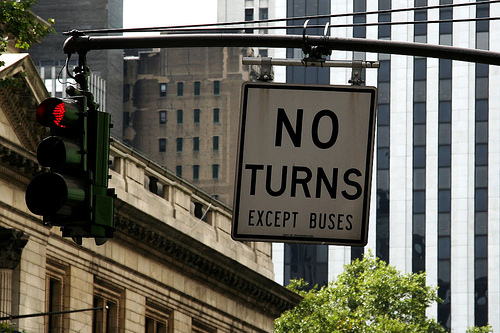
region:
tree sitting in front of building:
[270, 256, 496, 331]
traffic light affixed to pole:
[20, 26, 495, 247]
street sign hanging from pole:
[229, 57, 386, 239]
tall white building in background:
[213, 0, 498, 332]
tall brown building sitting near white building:
[122, 30, 268, 245]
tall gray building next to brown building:
[0, 0, 122, 141]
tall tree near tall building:
[0, 0, 54, 63]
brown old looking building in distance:
[116, 22, 273, 259]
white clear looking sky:
[116, 0, 227, 40]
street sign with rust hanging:
[227, 85, 379, 238]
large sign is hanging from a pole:
[231, 30, 381, 250]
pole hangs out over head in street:
[61, 20, 496, 72]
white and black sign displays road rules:
[227, 41, 377, 243]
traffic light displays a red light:
[18, 91, 119, 246]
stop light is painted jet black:
[18, 25, 125, 249]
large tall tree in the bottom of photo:
[273, 251, 494, 332]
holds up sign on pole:
[240, 23, 375, 84]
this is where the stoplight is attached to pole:
[54, 28, 100, 92]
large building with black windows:
[272, 0, 498, 329]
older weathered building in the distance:
[118, 22, 270, 214]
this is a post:
[228, 79, 369, 241]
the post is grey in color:
[340, 94, 367, 138]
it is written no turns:
[244, 95, 369, 212]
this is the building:
[112, 185, 217, 330]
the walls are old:
[155, 275, 191, 300]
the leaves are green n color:
[333, 271, 409, 331]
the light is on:
[38, 98, 70, 133]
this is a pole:
[317, 32, 374, 59]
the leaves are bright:
[344, 266, 409, 330]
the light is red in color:
[49, 101, 62, 118]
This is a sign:
[177, 49, 479, 331]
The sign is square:
[267, 53, 329, 234]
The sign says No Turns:
[208, 119, 347, 292]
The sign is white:
[265, 187, 365, 274]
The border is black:
[195, 50, 362, 330]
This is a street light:
[25, 86, 145, 328]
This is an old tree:
[180, 262, 380, 329]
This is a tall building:
[375, 116, 498, 226]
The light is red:
[55, 101, 99, 151]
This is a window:
[110, 82, 179, 135]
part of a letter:
[271, 86, 306, 154]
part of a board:
[313, 227, 333, 249]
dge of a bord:
[293, 223, 320, 258]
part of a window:
[433, 199, 450, 232]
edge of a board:
[318, 240, 334, 252]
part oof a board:
[304, 205, 354, 277]